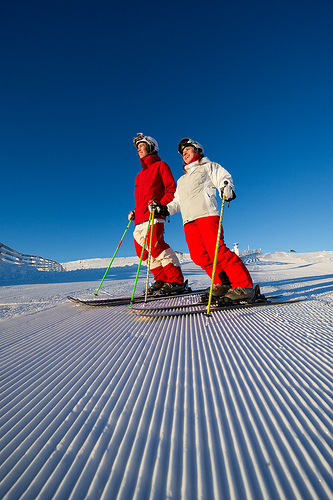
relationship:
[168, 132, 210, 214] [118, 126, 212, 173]
girl with helmet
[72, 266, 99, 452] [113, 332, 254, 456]
lines on ground